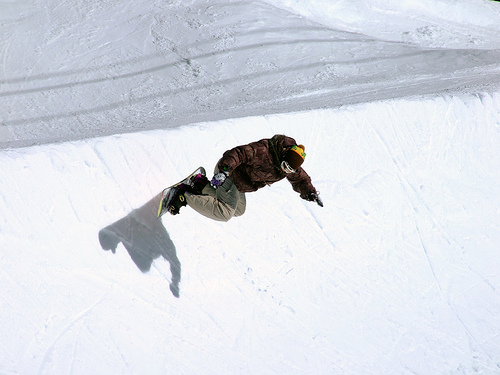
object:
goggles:
[277, 160, 299, 175]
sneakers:
[163, 183, 198, 216]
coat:
[210, 134, 319, 202]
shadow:
[0, 0, 499, 150]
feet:
[164, 189, 190, 214]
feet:
[187, 172, 209, 195]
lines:
[0, 49, 442, 129]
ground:
[0, 1, 499, 372]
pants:
[183, 176, 247, 222]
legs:
[188, 179, 241, 224]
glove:
[209, 170, 229, 190]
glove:
[303, 187, 322, 210]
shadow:
[98, 187, 184, 298]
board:
[154, 166, 208, 222]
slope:
[0, 92, 499, 373]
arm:
[285, 169, 316, 197]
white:
[312, 262, 477, 339]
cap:
[280, 142, 309, 172]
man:
[166, 134, 324, 222]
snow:
[0, 0, 498, 374]